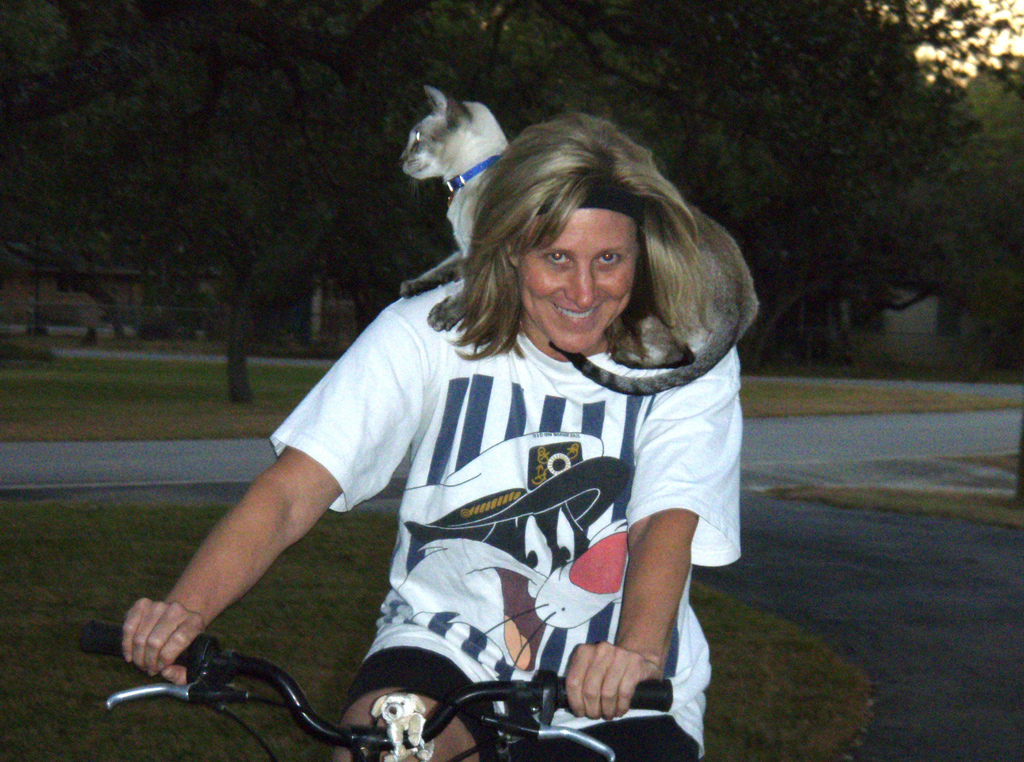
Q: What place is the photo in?
A: It is at the city.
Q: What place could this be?
A: It is a city.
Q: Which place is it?
A: It is a city.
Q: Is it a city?
A: Yes, it is a city.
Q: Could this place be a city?
A: Yes, it is a city.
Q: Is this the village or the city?
A: It is the city.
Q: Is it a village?
A: No, it is a city.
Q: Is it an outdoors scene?
A: Yes, it is outdoors.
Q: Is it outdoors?
A: Yes, it is outdoors.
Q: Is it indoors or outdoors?
A: It is outdoors.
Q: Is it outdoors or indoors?
A: It is outdoors.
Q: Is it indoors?
A: No, it is outdoors.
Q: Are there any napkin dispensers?
A: No, there are no napkin dispensers.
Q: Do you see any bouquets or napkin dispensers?
A: No, there are no napkin dispensers or bouquets.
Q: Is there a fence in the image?
A: No, there are no fences.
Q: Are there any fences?
A: No, there are no fences.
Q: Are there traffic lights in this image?
A: No, there are no traffic lights.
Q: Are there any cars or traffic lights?
A: No, there are no traffic lights or cars.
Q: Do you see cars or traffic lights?
A: No, there are no traffic lights or cars.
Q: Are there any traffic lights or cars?
A: No, there are no traffic lights or cars.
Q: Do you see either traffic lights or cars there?
A: No, there are no traffic lights or cars.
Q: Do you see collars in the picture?
A: Yes, there is a collar.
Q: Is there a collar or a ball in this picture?
A: Yes, there is a collar.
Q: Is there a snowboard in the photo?
A: No, there are no snowboards.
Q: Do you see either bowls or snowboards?
A: No, there are no snowboards or bowls.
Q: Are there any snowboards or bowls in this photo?
A: No, there are no snowboards or bowls.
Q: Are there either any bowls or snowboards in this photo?
A: No, there are no snowboards or bowls.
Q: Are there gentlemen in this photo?
A: No, there are no gentlemen.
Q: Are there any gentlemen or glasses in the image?
A: No, there are no gentlemen or glasses.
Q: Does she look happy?
A: Yes, the lady is happy.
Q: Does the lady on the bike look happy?
A: Yes, the lady is happy.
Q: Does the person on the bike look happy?
A: Yes, the lady is happy.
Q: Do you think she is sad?
A: No, the lady is happy.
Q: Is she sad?
A: No, the lady is happy.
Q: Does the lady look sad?
A: No, the lady is happy.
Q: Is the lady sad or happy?
A: The lady is happy.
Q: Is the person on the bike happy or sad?
A: The lady is happy.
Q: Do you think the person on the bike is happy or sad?
A: The lady is happy.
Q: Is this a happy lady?
A: Yes, this is a happy lady.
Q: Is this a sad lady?
A: No, this is a happy lady.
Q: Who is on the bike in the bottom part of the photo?
A: The lady is on the bike.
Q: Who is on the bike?
A: The lady is on the bike.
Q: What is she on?
A: The lady is on the bike.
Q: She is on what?
A: The lady is on the bike.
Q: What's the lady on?
A: The lady is on the bike.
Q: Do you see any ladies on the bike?
A: Yes, there is a lady on the bike.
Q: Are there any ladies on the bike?
A: Yes, there is a lady on the bike.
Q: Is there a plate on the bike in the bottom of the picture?
A: No, there is a lady on the bike.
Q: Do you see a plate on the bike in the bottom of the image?
A: No, there is a lady on the bike.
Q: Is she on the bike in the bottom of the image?
A: Yes, the lady is on the bike.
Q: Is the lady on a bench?
A: No, the lady is on the bike.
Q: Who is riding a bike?
A: The lady is riding a bike.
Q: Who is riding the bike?
A: The lady is riding a bike.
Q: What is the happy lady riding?
A: The lady is riding a bike.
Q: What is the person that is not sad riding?
A: The lady is riding a bike.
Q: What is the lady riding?
A: The lady is riding a bike.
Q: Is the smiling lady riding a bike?
A: Yes, the lady is riding a bike.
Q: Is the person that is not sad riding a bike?
A: Yes, the lady is riding a bike.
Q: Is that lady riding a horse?
A: No, the lady is riding a bike.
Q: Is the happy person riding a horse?
A: No, the lady is riding a bike.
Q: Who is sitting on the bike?
A: The lady is sitting on the bike.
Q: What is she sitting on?
A: The lady is sitting on the bike.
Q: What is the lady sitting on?
A: The lady is sitting on the bike.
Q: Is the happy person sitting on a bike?
A: Yes, the lady is sitting on a bike.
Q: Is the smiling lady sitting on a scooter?
A: No, the lady is sitting on a bike.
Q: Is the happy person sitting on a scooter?
A: No, the lady is sitting on a bike.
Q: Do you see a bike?
A: Yes, there is a bike.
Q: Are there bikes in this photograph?
A: Yes, there is a bike.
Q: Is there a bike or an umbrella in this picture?
A: Yes, there is a bike.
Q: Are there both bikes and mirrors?
A: No, there is a bike but no mirrors.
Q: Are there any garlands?
A: No, there are no garlands.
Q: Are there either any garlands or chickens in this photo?
A: No, there are no garlands or chickens.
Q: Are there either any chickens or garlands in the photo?
A: No, there are no garlands or chickens.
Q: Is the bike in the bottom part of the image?
A: Yes, the bike is in the bottom of the image.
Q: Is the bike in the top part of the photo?
A: No, the bike is in the bottom of the image.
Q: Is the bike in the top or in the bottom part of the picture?
A: The bike is in the bottom of the image.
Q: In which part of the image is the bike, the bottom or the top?
A: The bike is in the bottom of the image.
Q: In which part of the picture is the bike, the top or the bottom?
A: The bike is in the bottom of the image.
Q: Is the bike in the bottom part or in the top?
A: The bike is in the bottom of the image.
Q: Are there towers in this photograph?
A: No, there are no towers.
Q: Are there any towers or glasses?
A: No, there are no towers or glasses.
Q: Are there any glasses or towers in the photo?
A: No, there are no towers or glasses.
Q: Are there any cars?
A: No, there are no cars.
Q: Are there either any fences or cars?
A: No, there are no cars or fences.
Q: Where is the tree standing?
A: The tree is standing in the city.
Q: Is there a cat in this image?
A: Yes, there is a cat.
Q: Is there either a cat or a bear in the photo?
A: Yes, there is a cat.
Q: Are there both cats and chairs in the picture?
A: No, there is a cat but no chairs.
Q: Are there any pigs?
A: No, there are no pigs.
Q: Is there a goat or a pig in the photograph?
A: No, there are no pigs or goats.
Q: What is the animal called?
A: The animal is a cat.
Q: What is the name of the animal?
A: The animal is a cat.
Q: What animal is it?
A: The animal is a cat.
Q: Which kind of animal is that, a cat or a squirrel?
A: This is a cat.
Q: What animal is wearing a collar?
A: The cat is wearing a collar.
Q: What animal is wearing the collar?
A: The cat is wearing a collar.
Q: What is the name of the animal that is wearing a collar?
A: The animal is a cat.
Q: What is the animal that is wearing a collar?
A: The animal is a cat.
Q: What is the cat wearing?
A: The cat is wearing a collar.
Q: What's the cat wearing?
A: The cat is wearing a collar.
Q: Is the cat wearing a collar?
A: Yes, the cat is wearing a collar.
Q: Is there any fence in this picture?
A: No, there are no fences.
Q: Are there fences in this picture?
A: No, there are no fences.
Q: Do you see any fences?
A: No, there are no fences.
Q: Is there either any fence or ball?
A: No, there are no fences or balls.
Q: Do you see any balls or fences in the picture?
A: No, there are no fences or balls.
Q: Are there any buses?
A: No, there are no buses.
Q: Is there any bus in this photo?
A: No, there are no buses.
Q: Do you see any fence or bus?
A: No, there are no buses or fences.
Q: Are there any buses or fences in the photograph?
A: No, there are no buses or fences.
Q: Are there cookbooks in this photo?
A: No, there are no cookbooks.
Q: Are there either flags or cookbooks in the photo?
A: No, there are no cookbooks or flags.